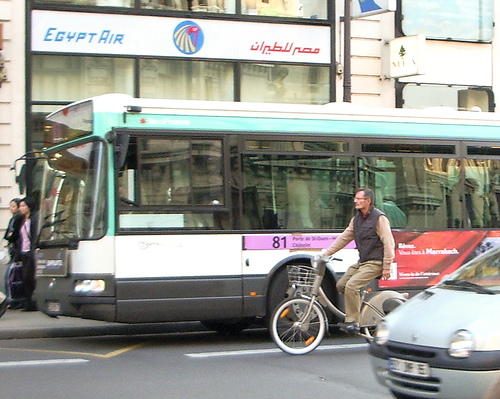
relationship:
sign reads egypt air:
[29, 8, 339, 69] [42, 26, 137, 50]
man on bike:
[316, 187, 395, 332] [271, 258, 410, 356]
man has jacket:
[316, 187, 395, 332] [353, 213, 388, 261]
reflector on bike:
[281, 309, 291, 319] [271, 258, 410, 356]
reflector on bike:
[304, 336, 315, 347] [271, 258, 410, 356]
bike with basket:
[271, 258, 410, 356] [286, 265, 321, 291]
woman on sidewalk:
[18, 200, 40, 311] [1, 308, 212, 337]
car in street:
[374, 242, 500, 399] [2, 330, 379, 398]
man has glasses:
[316, 187, 395, 332] [354, 196, 368, 200]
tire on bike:
[271, 297, 328, 357] [271, 258, 410, 356]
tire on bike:
[368, 288, 408, 340] [271, 258, 410, 356]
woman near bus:
[8, 198, 20, 263] [12, 94, 499, 336]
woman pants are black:
[8, 198, 20, 263] [8, 243, 21, 267]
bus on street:
[12, 94, 499, 336] [2, 330, 379, 398]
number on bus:
[270, 237, 291, 250] [12, 94, 499, 336]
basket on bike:
[286, 265, 321, 291] [271, 258, 410, 356]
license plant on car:
[387, 361, 430, 377] [374, 242, 500, 399]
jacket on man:
[353, 213, 388, 261] [316, 187, 395, 332]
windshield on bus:
[36, 141, 108, 240] [12, 94, 499, 336]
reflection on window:
[418, 156, 499, 224] [244, 154, 355, 228]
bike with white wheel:
[271, 258, 410, 356] [271, 297, 328, 357]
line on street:
[2, 359, 87, 366] [2, 330, 379, 398]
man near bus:
[316, 187, 395, 332] [12, 94, 499, 336]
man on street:
[316, 187, 395, 332] [2, 330, 379, 398]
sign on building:
[29, 8, 339, 69] [2, 1, 500, 121]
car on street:
[374, 242, 500, 399] [2, 330, 379, 398]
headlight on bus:
[73, 281, 106, 294] [12, 94, 499, 336]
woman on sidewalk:
[8, 198, 20, 263] [1, 308, 212, 337]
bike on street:
[271, 258, 410, 356] [2, 330, 379, 398]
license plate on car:
[387, 361, 430, 377] [374, 242, 500, 399]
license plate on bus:
[46, 301, 63, 314] [12, 94, 499, 336]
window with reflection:
[244, 154, 355, 228] [418, 156, 499, 224]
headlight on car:
[449, 336, 464, 359] [374, 242, 500, 399]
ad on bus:
[244, 228, 499, 293] [12, 94, 499, 336]